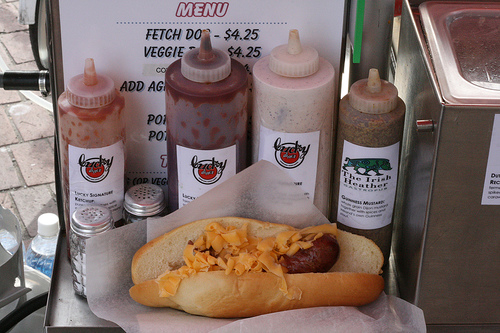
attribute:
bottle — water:
[30, 212, 58, 282]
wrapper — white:
[75, 222, 135, 329]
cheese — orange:
[150, 217, 344, 304]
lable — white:
[161, 130, 261, 201]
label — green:
[336, 139, 400, 231]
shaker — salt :
[69, 209, 121, 307]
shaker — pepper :
[123, 182, 168, 229]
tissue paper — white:
[81, 160, 428, 331]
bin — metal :
[396, 2, 498, 332]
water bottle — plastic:
[14, 203, 59, 296]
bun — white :
[172, 275, 377, 316]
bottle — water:
[18, 209, 65, 274]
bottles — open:
[164, 25, 249, 227]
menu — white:
[78, 3, 336, 198]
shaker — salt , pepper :
[69, 180, 171, 296]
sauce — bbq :
[158, 24, 250, 224]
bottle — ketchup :
[58, 62, 137, 256]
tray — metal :
[28, 188, 409, 330]